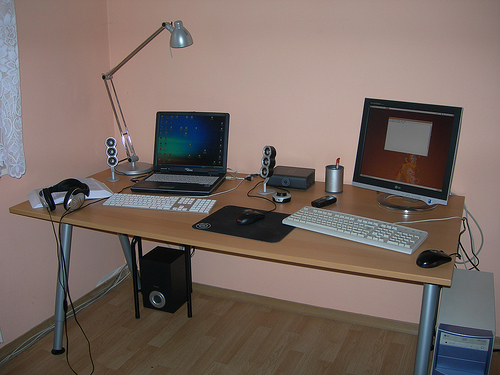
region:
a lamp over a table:
[82, 5, 198, 185]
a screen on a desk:
[345, 90, 465, 220]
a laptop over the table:
[125, 105, 236, 196]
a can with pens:
[317, 150, 343, 195]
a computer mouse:
[412, 241, 448, 272]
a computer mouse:
[55, 182, 82, 212]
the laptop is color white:
[276, 195, 431, 258]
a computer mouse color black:
[189, 195, 295, 245]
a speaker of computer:
[102, 130, 122, 181]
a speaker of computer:
[251, 138, 278, 197]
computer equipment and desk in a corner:
[7, 5, 497, 366]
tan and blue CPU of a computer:
[426, 269, 494, 371]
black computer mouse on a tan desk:
[413, 248, 450, 268]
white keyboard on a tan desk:
[285, 204, 426, 259]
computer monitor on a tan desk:
[350, 94, 462, 209]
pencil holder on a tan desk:
[324, 158, 344, 195]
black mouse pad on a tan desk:
[193, 204, 295, 244]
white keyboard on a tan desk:
[101, 188, 215, 218]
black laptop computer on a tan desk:
[130, 109, 230, 196]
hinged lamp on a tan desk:
[101, 18, 196, 179]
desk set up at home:
[17, 8, 474, 372]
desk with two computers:
[63, 17, 490, 344]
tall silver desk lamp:
[96, 3, 195, 190]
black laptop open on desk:
[131, 98, 241, 198]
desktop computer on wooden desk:
[305, 76, 469, 283]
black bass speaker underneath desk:
[133, 236, 196, 319]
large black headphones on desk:
[31, 168, 103, 225]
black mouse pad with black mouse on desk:
[206, 185, 295, 263]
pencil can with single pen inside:
[326, 148, 348, 200]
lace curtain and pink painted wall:
[1, 0, 86, 176]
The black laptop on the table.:
[131, 107, 235, 192]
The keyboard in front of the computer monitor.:
[292, 205, 422, 252]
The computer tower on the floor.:
[440, 263, 494, 374]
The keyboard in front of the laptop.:
[105, 188, 215, 215]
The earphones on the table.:
[37, 175, 88, 214]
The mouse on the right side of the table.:
[413, 240, 453, 266]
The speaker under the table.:
[142, 250, 188, 311]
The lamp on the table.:
[100, 22, 195, 177]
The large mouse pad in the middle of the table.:
[195, 202, 293, 244]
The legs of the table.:
[47, 221, 436, 373]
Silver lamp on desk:
[81, 8, 209, 185]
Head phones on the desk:
[28, 170, 102, 227]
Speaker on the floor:
[131, 242, 223, 334]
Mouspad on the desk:
[191, 193, 299, 254]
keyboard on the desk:
[100, 185, 220, 225]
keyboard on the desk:
[278, 195, 433, 265]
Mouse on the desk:
[413, 240, 458, 282]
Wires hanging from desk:
[453, 197, 493, 277]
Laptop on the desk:
[131, 98, 236, 197]